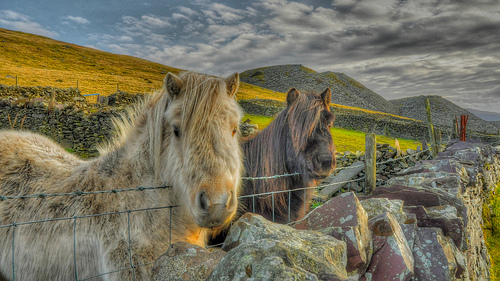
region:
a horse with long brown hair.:
[4, 62, 256, 279]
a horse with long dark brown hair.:
[223, 88, 358, 233]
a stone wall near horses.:
[151, 140, 498, 280]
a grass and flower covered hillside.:
[1, 29, 497, 145]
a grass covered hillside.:
[221, 62, 498, 123]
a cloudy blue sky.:
[1, 0, 495, 115]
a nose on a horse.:
[181, 192, 248, 229]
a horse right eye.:
[160, 108, 195, 153]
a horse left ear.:
[315, 80, 337, 119]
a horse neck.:
[98, 143, 155, 280]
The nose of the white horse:
[195, 186, 238, 210]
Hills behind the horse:
[253, 61, 473, 118]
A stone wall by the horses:
[347, 153, 485, 265]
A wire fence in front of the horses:
[17, 193, 159, 258]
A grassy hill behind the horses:
[14, 44, 114, 84]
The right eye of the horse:
[164, 120, 194, 135]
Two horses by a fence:
[0, 75, 362, 271]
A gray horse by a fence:
[244, 88, 336, 209]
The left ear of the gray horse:
[322, 85, 331, 107]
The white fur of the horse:
[19, 138, 53, 162]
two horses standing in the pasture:
[5, 67, 375, 280]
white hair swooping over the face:
[172, 71, 236, 154]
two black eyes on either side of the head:
[162, 118, 247, 145]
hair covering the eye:
[285, 84, 326, 154]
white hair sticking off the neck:
[83, 97, 142, 159]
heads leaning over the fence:
[115, 68, 357, 225]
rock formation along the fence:
[139, 129, 499, 280]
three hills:
[243, 52, 474, 125]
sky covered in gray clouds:
[4, 0, 499, 110]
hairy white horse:
[3, 70, 255, 280]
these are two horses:
[1, 85, 350, 211]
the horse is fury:
[0, 62, 246, 244]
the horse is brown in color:
[189, 125, 230, 176]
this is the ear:
[161, 67, 188, 93]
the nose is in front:
[193, 186, 237, 210]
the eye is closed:
[282, 103, 312, 145]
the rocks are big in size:
[341, 173, 453, 264]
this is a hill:
[268, 65, 347, 84]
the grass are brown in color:
[33, 45, 87, 79]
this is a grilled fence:
[80, 186, 152, 278]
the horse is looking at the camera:
[0, 55, 262, 221]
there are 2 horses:
[19, 51, 363, 211]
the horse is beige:
[2, 67, 262, 253]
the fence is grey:
[2, 179, 193, 256]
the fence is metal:
[0, 167, 176, 238]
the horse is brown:
[244, 82, 342, 190]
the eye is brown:
[212, 114, 253, 143]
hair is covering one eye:
[264, 97, 345, 153]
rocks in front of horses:
[252, 181, 492, 271]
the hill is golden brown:
[4, 27, 162, 88]